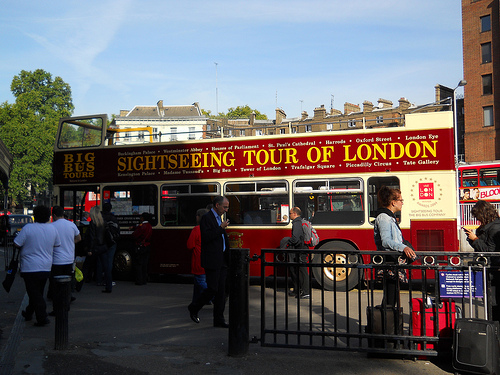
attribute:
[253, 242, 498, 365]
gate — black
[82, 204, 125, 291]
woman —  blond 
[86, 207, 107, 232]
blond hair —  long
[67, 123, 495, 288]
bus —  for tour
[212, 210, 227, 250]
shirt — blue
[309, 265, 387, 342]
fence — metallic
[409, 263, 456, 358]
suitcase — red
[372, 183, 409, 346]
woman — red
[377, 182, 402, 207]
hair — long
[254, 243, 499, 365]
baracade — iron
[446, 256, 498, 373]
suitcase — black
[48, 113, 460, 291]
bus — double-decker, red,  for tour,  guided,  of London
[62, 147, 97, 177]
print — yellow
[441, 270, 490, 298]
sign — blue, white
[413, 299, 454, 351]
bag — red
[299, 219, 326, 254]
backpack — man's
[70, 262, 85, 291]
hat —  yellow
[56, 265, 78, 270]
loop —  belt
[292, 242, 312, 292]
pants —  black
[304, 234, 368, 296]
tire — black